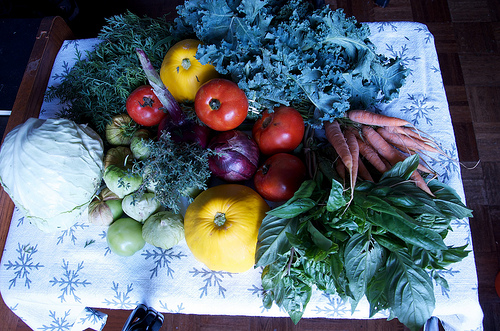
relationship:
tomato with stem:
[123, 85, 164, 124] [137, 99, 159, 110]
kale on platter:
[179, 2, 406, 119] [9, 17, 472, 329]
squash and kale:
[154, 39, 213, 93] [179, 2, 406, 119]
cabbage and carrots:
[3, 114, 105, 228] [256, 11, 444, 210]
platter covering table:
[9, 17, 472, 329] [0, 12, 485, 330]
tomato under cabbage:
[92, 191, 123, 226] [3, 114, 105, 228]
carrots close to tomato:
[256, 11, 444, 210] [252, 110, 306, 150]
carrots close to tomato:
[256, 11, 444, 210] [255, 153, 307, 198]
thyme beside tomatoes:
[53, 11, 176, 124] [125, 81, 308, 203]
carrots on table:
[256, 11, 444, 210] [0, 12, 485, 330]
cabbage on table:
[3, 114, 105, 228] [0, 12, 485, 330]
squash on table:
[154, 39, 213, 93] [0, 12, 485, 330]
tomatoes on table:
[125, 81, 308, 203] [0, 12, 485, 330]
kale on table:
[179, 2, 406, 119] [0, 12, 485, 330]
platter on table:
[9, 17, 472, 329] [0, 12, 485, 330]